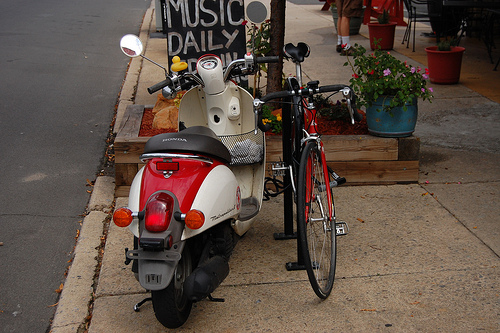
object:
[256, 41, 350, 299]
bicycle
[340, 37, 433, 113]
plant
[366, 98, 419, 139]
pot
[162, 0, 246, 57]
writing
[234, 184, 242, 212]
design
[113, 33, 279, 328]
scooter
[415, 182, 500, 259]
cracks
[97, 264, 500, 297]
cracks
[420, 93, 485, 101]
cracks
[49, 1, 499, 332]
pavement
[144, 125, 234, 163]
writing/seat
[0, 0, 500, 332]
road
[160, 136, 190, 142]
writing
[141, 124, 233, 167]
scooter seat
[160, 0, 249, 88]
sign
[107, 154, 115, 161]
trash